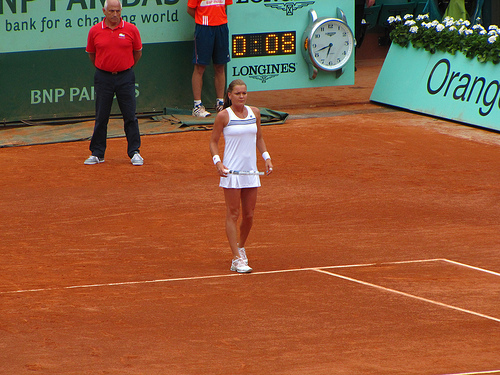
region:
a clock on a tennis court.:
[291, 7, 373, 99]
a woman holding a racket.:
[196, 79, 287, 282]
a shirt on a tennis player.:
[219, 100, 264, 170]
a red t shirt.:
[83, 11, 150, 72]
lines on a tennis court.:
[0, 253, 499, 322]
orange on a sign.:
[420, 50, 498, 127]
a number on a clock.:
[225, 23, 302, 68]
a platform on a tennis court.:
[148, 94, 298, 144]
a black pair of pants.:
[84, 66, 156, 161]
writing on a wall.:
[20, 70, 142, 111]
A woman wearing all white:
[207, 79, 274, 274]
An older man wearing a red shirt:
[84, 0, 143, 165]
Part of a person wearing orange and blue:
[185, 0, 230, 117]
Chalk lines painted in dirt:
[0, 254, 499, 325]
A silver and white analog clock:
[302, 9, 354, 81]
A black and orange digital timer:
[232, 31, 296, 57]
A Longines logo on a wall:
[231, 62, 298, 82]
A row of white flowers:
[386, 11, 498, 63]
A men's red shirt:
[84, 19, 143, 72]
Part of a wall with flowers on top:
[368, 14, 498, 134]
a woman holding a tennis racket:
[194, 62, 280, 286]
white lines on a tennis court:
[263, 242, 485, 334]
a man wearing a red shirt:
[79, 4, 144, 68]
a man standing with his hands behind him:
[71, 0, 164, 98]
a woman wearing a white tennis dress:
[213, 66, 266, 202]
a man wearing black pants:
[81, 4, 146, 171]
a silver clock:
[287, 12, 362, 91]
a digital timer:
[211, 20, 308, 76]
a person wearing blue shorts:
[173, 2, 245, 77]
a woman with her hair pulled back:
[211, 75, 270, 131]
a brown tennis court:
[2, 117, 497, 372]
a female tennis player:
[207, 78, 277, 278]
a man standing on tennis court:
[79, 0, 146, 165]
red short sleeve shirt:
[84, 19, 144, 74]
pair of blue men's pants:
[86, 68, 141, 158]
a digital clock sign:
[226, 31, 300, 58]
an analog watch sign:
[305, 9, 359, 79]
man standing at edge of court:
[186, 0, 236, 117]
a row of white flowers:
[381, 10, 498, 62]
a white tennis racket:
[219, 168, 261, 175]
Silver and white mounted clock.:
[303, 5, 363, 82]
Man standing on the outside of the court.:
[68, 0, 148, 169]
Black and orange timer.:
[231, 27, 300, 62]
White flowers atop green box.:
[386, 5, 497, 65]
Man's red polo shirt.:
[82, 19, 146, 74]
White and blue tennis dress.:
[215, 106, 266, 193]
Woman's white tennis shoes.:
[217, 246, 257, 275]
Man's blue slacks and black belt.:
[81, 63, 141, 155]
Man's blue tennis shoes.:
[78, 147, 148, 169]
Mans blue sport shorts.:
[186, 20, 234, 69]